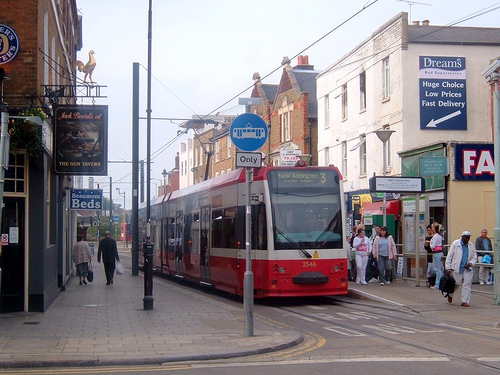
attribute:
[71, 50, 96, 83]
statue — gold, chicken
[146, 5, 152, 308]
post — metal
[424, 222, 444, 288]
two woman — standing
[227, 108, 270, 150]
circular sign — blue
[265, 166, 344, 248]
window — Large 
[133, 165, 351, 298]
bus — transit, red, white, large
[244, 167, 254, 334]
post — metal, grey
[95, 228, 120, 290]
person — dressed up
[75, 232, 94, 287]
person — dressed up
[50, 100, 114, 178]
sign — hanging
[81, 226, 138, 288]
man — walking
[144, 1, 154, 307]
lamp post — black, metal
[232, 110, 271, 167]
sign — destination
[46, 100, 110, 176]
sign — rectangular, black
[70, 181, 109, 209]
sign — rectangular, black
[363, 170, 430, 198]
sign — rectangular, black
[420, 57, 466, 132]
sign — white, blue, rectangle, large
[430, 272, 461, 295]
suitcase — black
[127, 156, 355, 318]
trolly — red, white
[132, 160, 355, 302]
train — trolley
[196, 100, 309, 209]
sign — blue, white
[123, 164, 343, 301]
tran — white, red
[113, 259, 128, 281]
bag — shopping